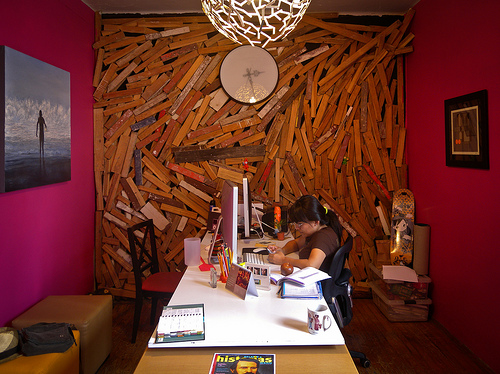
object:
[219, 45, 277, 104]
clock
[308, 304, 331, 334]
coffee mug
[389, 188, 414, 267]
skateboard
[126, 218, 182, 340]
chair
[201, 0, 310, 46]
light fixture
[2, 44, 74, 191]
photo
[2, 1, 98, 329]
wall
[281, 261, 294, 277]
apple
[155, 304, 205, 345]
appointment book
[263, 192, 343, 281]
person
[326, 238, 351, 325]
chair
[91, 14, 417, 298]
wall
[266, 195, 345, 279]
woman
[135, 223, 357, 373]
desk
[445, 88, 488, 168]
artwork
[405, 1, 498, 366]
wall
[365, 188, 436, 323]
clutter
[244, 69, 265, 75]
minute hand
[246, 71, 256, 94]
hour hand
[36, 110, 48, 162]
person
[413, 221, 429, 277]
cardboard tube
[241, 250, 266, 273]
keyboard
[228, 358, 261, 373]
man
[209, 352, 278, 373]
magazine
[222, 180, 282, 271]
desktop computer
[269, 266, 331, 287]
notebook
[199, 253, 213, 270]
flyswatter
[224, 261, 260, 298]
calender